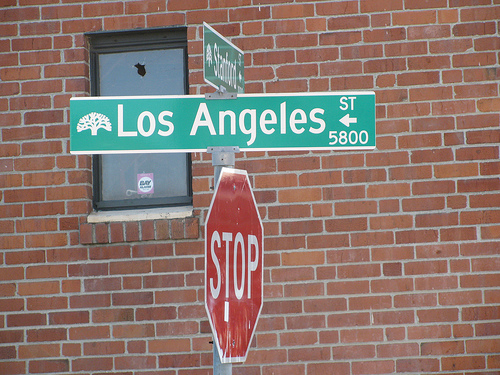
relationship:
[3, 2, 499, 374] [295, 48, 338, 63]
building has brick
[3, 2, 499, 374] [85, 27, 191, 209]
building has window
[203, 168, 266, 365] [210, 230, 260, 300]
sign has word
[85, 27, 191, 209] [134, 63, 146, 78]
window has hole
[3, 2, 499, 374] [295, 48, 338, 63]
wall has brick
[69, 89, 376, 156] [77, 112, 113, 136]
sign has tree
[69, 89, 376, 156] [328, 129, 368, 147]
sign has street number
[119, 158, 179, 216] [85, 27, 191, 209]
sticker in window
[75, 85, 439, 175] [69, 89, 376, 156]
name on sign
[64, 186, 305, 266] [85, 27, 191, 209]
ledge on window